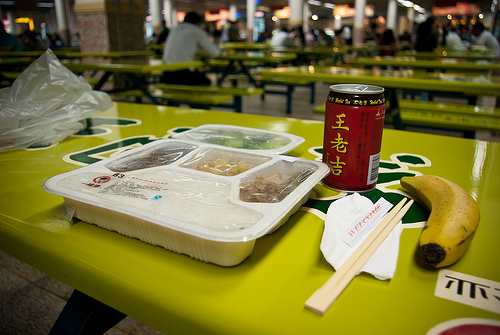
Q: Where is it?
A: This is at the cafeteria.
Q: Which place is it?
A: It is a cafeteria.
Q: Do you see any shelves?
A: No, there are no shelves.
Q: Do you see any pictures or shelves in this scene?
A: No, there are no shelves or pictures.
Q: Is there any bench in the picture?
A: Yes, there is a bench.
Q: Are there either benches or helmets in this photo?
A: Yes, there is a bench.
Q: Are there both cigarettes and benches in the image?
A: No, there is a bench but no cigarettes.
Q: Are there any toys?
A: No, there are no toys.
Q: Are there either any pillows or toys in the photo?
A: No, there are no toys or pillows.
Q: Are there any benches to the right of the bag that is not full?
A: Yes, there is a bench to the right of the bag.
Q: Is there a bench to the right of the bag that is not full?
A: Yes, there is a bench to the right of the bag.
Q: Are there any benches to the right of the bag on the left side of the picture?
A: Yes, there is a bench to the right of the bag.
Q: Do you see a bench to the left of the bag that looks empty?
A: No, the bench is to the right of the bag.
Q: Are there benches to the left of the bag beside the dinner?
A: No, the bench is to the right of the bag.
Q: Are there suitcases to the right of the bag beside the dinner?
A: No, there is a bench to the right of the bag.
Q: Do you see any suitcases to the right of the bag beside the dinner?
A: No, there is a bench to the right of the bag.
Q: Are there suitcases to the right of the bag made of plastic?
A: No, there is a bench to the right of the bag.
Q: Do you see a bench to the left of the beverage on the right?
A: Yes, there is a bench to the left of the beverage.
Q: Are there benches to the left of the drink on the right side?
A: Yes, there is a bench to the left of the beverage.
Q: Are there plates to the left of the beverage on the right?
A: No, there is a bench to the left of the beverage.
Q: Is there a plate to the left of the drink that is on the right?
A: No, there is a bench to the left of the beverage.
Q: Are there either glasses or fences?
A: No, there are no glasses or fences.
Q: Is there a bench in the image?
A: Yes, there is a bench.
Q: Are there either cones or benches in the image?
A: Yes, there is a bench.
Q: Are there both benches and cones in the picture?
A: No, there is a bench but no cones.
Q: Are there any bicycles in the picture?
A: No, there are no bicycles.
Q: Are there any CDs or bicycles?
A: No, there are no bicycles or cds.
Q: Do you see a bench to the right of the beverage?
A: Yes, there is a bench to the right of the beverage.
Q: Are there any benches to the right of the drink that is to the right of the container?
A: Yes, there is a bench to the right of the beverage.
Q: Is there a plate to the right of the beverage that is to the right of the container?
A: No, there is a bench to the right of the beverage.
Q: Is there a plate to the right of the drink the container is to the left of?
A: No, there is a bench to the right of the beverage.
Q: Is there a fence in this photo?
A: No, there are no fences.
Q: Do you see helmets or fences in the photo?
A: No, there are no fences or helmets.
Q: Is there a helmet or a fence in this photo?
A: No, there are no fences or helmets.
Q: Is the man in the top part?
A: Yes, the man is in the top of the image.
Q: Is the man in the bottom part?
A: No, the man is in the top of the image.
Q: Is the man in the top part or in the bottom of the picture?
A: The man is in the top of the image.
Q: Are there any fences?
A: No, there are no fences.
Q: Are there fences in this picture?
A: No, there are no fences.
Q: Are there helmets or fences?
A: No, there are no fences or helmets.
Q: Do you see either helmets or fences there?
A: No, there are no fences or helmets.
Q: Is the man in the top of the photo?
A: Yes, the man is in the top of the image.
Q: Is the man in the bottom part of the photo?
A: No, the man is in the top of the image.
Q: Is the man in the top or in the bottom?
A: The man is in the top of the image.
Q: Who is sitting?
A: The man is sitting.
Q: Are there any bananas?
A: Yes, there is a banana.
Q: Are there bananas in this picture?
A: Yes, there is a banana.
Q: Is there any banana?
A: Yes, there is a banana.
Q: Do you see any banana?
A: Yes, there is a banana.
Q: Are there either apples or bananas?
A: Yes, there is a banana.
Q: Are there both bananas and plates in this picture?
A: No, there is a banana but no plates.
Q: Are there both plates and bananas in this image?
A: No, there is a banana but no plates.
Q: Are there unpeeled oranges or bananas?
A: Yes, there is an unpeeled banana.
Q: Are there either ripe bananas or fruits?
A: Yes, there is a ripe banana.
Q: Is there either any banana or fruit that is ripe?
A: Yes, the banana is ripe.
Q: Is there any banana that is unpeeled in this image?
A: Yes, there is an unpeeled banana.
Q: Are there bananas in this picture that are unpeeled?
A: Yes, there is a banana that is unpeeled.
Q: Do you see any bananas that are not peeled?
A: Yes, there is a unpeeled banana.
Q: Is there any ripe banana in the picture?
A: Yes, there is a ripe banana.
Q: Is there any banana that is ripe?
A: Yes, there is a banana that is ripe.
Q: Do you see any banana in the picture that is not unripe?
A: Yes, there is an ripe banana.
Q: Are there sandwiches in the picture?
A: No, there are no sandwiches.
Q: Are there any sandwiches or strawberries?
A: No, there are no sandwiches or strawberries.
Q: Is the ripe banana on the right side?
A: Yes, the banana is on the right of the image.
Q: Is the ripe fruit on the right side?
A: Yes, the banana is on the right of the image.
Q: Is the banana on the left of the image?
A: No, the banana is on the right of the image.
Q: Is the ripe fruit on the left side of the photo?
A: No, the banana is on the right of the image.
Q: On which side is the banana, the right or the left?
A: The banana is on the right of the image.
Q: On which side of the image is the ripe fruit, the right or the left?
A: The banana is on the right of the image.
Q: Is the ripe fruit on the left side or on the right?
A: The banana is on the right of the image.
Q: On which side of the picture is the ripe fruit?
A: The banana is on the right of the image.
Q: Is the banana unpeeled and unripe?
A: No, the banana is unpeeled but ripe.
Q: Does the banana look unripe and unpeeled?
A: No, the banana is unpeeled but ripe.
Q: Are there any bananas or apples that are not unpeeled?
A: No, there is a banana but it is unpeeled.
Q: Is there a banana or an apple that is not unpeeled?
A: No, there is a banana but it is unpeeled.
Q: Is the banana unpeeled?
A: Yes, the banana is unpeeled.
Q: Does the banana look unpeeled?
A: Yes, the banana is unpeeled.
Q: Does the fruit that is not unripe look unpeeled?
A: Yes, the banana is unpeeled.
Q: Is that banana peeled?
A: No, the banana is unpeeled.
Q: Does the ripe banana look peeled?
A: No, the banana is unpeeled.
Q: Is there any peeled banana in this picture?
A: No, there is a banana but it is unpeeled.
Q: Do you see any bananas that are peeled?
A: No, there is a banana but it is unpeeled.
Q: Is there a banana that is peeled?
A: No, there is a banana but it is unpeeled.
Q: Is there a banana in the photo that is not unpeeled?
A: No, there is a banana but it is unpeeled.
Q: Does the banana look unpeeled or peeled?
A: The banana is unpeeled.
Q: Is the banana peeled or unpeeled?
A: The banana is unpeeled.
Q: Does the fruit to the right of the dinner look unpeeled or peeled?
A: The banana is unpeeled.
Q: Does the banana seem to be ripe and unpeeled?
A: Yes, the banana is ripe and unpeeled.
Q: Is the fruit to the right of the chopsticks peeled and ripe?
A: No, the banana is ripe but unpeeled.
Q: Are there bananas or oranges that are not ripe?
A: No, there is a banana but it is ripe.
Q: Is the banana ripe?
A: Yes, the banana is ripe.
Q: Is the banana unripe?
A: No, the banana is ripe.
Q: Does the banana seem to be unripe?
A: No, the banana is ripe.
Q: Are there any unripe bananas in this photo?
A: No, there is a banana but it is ripe.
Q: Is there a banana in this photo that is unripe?
A: No, there is a banana but it is ripe.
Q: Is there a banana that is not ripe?
A: No, there is a banana but it is ripe.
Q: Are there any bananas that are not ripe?
A: No, there is a banana but it is ripe.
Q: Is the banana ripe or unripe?
A: The banana is ripe.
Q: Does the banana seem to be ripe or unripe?
A: The banana is ripe.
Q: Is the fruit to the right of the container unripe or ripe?
A: The banana is ripe.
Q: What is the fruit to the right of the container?
A: The fruit is a banana.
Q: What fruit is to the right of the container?
A: The fruit is a banana.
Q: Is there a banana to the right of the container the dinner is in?
A: Yes, there is a banana to the right of the container.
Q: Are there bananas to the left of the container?
A: No, the banana is to the right of the container.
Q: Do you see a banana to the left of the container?
A: No, the banana is to the right of the container.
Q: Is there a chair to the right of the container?
A: No, there is a banana to the right of the container.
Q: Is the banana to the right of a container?
A: Yes, the banana is to the right of a container.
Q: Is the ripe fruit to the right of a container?
A: Yes, the banana is to the right of a container.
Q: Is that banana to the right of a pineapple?
A: No, the banana is to the right of a container.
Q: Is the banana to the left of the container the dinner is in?
A: No, the banana is to the right of the container.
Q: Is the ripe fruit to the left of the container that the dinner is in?
A: No, the banana is to the right of the container.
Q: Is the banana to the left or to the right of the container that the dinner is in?
A: The banana is to the right of the container.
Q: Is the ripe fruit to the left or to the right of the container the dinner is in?
A: The banana is to the right of the container.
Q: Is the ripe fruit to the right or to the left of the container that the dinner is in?
A: The banana is to the right of the container.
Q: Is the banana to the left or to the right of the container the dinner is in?
A: The banana is to the right of the container.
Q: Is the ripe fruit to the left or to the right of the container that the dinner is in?
A: The banana is to the right of the container.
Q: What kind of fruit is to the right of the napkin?
A: The fruit is a banana.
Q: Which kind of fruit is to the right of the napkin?
A: The fruit is a banana.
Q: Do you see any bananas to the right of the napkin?
A: Yes, there is a banana to the right of the napkin.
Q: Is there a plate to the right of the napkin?
A: No, there is a banana to the right of the napkin.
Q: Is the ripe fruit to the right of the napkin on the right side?
A: Yes, the banana is to the right of the napkin.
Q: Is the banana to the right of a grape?
A: No, the banana is to the right of the napkin.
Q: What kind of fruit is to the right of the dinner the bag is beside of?
A: The fruit is a banana.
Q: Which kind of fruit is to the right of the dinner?
A: The fruit is a banana.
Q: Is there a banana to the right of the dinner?
A: Yes, there is a banana to the right of the dinner.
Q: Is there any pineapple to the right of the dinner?
A: No, there is a banana to the right of the dinner.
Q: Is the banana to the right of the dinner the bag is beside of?
A: Yes, the banana is to the right of the dinner.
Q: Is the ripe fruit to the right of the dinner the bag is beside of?
A: Yes, the banana is to the right of the dinner.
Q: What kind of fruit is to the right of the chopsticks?
A: The fruit is a banana.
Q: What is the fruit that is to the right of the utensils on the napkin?
A: The fruit is a banana.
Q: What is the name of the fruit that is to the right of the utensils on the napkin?
A: The fruit is a banana.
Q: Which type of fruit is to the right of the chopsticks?
A: The fruit is a banana.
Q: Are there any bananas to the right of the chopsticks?
A: Yes, there is a banana to the right of the chopsticks.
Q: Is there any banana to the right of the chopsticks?
A: Yes, there is a banana to the right of the chopsticks.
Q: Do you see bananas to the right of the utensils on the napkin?
A: Yes, there is a banana to the right of the chopsticks.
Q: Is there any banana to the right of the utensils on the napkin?
A: Yes, there is a banana to the right of the chopsticks.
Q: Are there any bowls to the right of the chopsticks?
A: No, there is a banana to the right of the chopsticks.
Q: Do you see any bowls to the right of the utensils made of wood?
A: No, there is a banana to the right of the chopsticks.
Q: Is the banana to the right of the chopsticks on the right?
A: Yes, the banana is to the right of the chopsticks.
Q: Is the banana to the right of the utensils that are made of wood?
A: Yes, the banana is to the right of the chopsticks.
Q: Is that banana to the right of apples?
A: No, the banana is to the right of the chopsticks.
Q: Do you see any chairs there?
A: No, there are no chairs.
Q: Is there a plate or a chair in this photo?
A: No, there are no chairs or plates.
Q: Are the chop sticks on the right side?
A: Yes, the chop sticks are on the right of the image.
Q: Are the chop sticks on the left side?
A: No, the chop sticks are on the right of the image.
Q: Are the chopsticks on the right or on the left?
A: The chopsticks are on the right of the image.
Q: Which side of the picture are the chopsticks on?
A: The chopsticks are on the right of the image.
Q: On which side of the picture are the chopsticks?
A: The chopsticks are on the right of the image.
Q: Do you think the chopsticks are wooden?
A: Yes, the chopsticks are wooden.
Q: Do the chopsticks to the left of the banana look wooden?
A: Yes, the chopsticks are wooden.